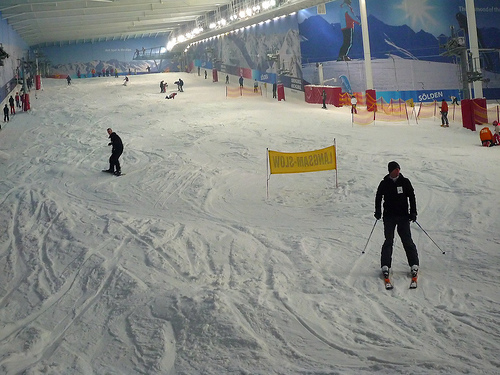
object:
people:
[165, 93, 177, 99]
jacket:
[108, 132, 124, 153]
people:
[123, 76, 129, 86]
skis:
[382, 265, 419, 290]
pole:
[361, 219, 378, 254]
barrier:
[321, 90, 327, 109]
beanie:
[388, 161, 401, 174]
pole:
[415, 220, 447, 255]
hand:
[408, 215, 417, 223]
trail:
[7, 178, 277, 368]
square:
[397, 186, 403, 193]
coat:
[374, 173, 418, 216]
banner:
[267, 138, 338, 200]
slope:
[0, 71, 500, 375]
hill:
[0, 72, 500, 375]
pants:
[381, 218, 420, 269]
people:
[174, 78, 184, 92]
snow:
[29, 180, 339, 362]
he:
[102, 128, 126, 177]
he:
[361, 161, 446, 290]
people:
[3, 77, 34, 122]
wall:
[181, 0, 499, 106]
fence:
[225, 85, 499, 132]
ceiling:
[0, 0, 232, 46]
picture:
[321, 90, 460, 128]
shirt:
[341, 12, 360, 30]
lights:
[157, 0, 296, 53]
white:
[266, 207, 319, 242]